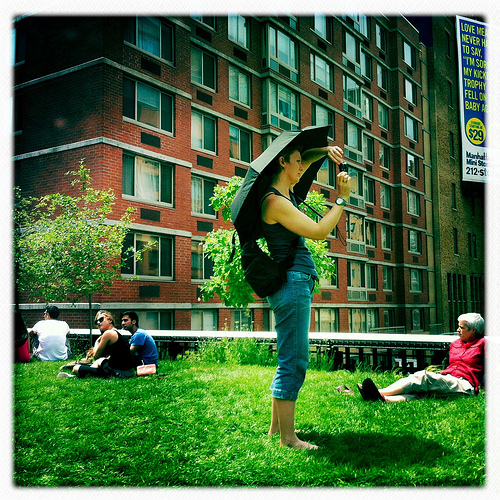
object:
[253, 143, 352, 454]
woman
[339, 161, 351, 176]
cell phone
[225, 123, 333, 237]
umbrella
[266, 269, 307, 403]
jeans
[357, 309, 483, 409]
man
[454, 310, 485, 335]
hair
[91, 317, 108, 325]
sunglasses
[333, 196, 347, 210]
wristwatch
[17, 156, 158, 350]
trees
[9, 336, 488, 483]
grass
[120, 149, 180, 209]
window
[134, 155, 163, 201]
curtains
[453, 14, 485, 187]
sign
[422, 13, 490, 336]
building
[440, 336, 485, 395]
shirt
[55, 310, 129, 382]
people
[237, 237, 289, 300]
purse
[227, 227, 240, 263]
string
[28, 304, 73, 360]
man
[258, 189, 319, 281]
tshirt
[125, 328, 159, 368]
shirt